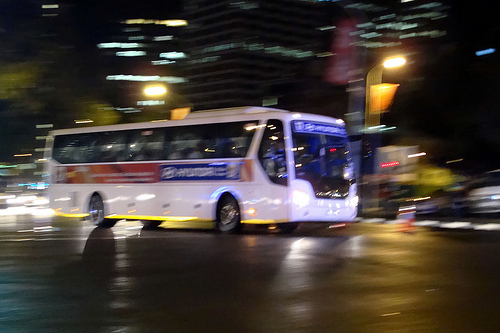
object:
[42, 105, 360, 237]
bus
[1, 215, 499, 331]
street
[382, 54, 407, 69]
street light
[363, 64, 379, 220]
pole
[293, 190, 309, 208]
front light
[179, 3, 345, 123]
building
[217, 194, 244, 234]
wheel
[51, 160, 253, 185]
advertisement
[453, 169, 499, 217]
car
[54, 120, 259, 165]
windows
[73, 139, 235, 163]
passengers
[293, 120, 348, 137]
marquee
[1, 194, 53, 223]
traffic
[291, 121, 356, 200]
windshield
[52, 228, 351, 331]
shadow